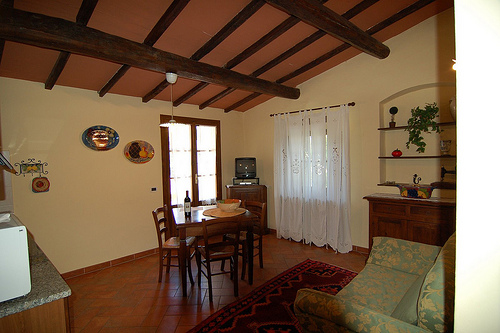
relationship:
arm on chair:
[296, 287, 372, 332] [292, 235, 456, 331]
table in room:
[149, 204, 273, 292] [95, 177, 338, 324]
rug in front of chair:
[182, 257, 357, 331] [292, 235, 456, 331]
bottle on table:
[184, 190, 191, 216] [165, 195, 259, 299]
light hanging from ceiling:
[161, 71, 181, 135] [167, 5, 269, 57]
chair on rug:
[144, 198, 205, 285] [184, 253, 359, 328]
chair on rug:
[241, 193, 271, 268] [184, 253, 359, 328]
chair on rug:
[188, 210, 253, 298] [184, 253, 359, 328]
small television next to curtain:
[234, 154, 256, 181] [271, 105, 353, 254]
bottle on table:
[184, 190, 191, 216] [171, 210, 194, 225]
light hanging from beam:
[161, 71, 181, 135] [74, 23, 346, 114]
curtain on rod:
[271, 105, 353, 254] [267, 104, 351, 120]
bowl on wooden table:
[216, 197, 242, 212] [136, 188, 282, 270]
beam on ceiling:
[3, 6, 300, 98] [0, 1, 452, 113]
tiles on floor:
[101, 280, 188, 331] [74, 270, 197, 332]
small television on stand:
[234, 157, 256, 177] [227, 178, 270, 188]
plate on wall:
[82, 124, 124, 150] [74, 101, 313, 231]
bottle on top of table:
[183, 190, 193, 218] [170, 202, 250, 294]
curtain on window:
[245, 107, 360, 263] [284, 134, 341, 202]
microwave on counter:
[1, 207, 35, 300] [2, 236, 79, 331]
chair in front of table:
[194, 218, 241, 301] [149, 154, 301, 273]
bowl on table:
[216, 199, 242, 212] [162, 200, 254, 262]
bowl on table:
[216, 199, 242, 212] [165, 207, 248, 256]